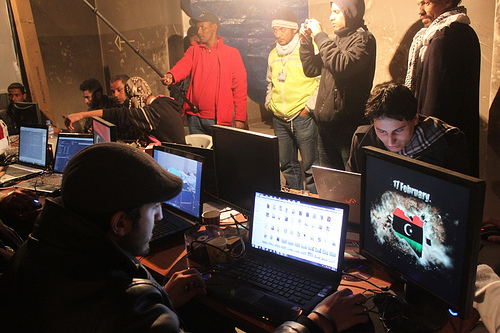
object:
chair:
[184, 133, 213, 150]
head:
[416, 0, 462, 29]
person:
[388, 0, 483, 174]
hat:
[270, 7, 303, 33]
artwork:
[188, 0, 306, 92]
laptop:
[0, 121, 48, 187]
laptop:
[148, 141, 214, 245]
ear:
[212, 23, 218, 31]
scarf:
[403, 5, 472, 94]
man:
[298, 0, 375, 195]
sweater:
[298, 26, 375, 122]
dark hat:
[58, 141, 183, 214]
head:
[56, 141, 184, 256]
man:
[0, 141, 370, 332]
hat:
[328, 0, 366, 37]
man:
[345, 81, 469, 176]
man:
[388, 0, 481, 176]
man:
[263, 9, 323, 194]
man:
[160, 9, 247, 134]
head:
[193, 13, 221, 44]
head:
[79, 78, 104, 109]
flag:
[391, 207, 425, 258]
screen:
[358, 148, 476, 304]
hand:
[159, 74, 174, 86]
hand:
[306, 288, 369, 331]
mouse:
[345, 293, 362, 305]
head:
[272, 10, 300, 46]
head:
[364, 81, 422, 154]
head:
[7, 82, 28, 103]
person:
[0, 82, 52, 138]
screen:
[250, 191, 344, 278]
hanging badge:
[277, 72, 285, 82]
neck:
[276, 32, 298, 56]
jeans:
[273, 114, 315, 193]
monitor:
[357, 146, 486, 321]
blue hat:
[193, 13, 220, 25]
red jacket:
[167, 35, 247, 125]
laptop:
[18, 131, 94, 196]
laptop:
[206, 188, 350, 324]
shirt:
[264, 33, 321, 122]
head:
[109, 73, 130, 104]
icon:
[266, 203, 270, 208]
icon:
[266, 212, 270, 217]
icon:
[285, 217, 289, 222]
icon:
[306, 212, 310, 217]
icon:
[317, 237, 321, 243]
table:
[0, 128, 499, 332]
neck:
[421, 7, 464, 34]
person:
[100, 74, 145, 142]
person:
[80, 78, 118, 131]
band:
[271, 20, 300, 29]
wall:
[0, 0, 499, 233]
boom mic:
[79, 0, 199, 110]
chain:
[277, 43, 299, 82]